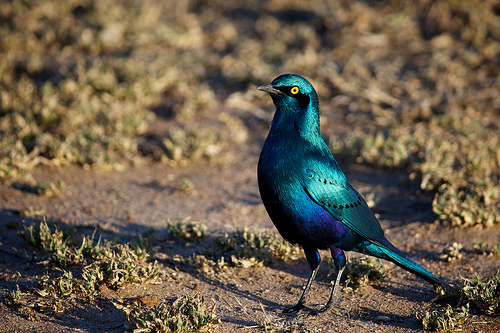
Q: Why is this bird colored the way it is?
A: To attract a mate.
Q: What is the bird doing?
A: Standing.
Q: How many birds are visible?
A: 1.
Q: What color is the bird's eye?
A: Yellow.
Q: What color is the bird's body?
A: Teal.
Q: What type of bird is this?
A: Starling.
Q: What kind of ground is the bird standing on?
A: Dirt.